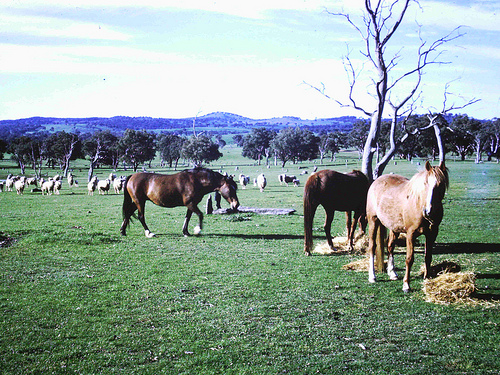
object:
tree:
[179, 137, 224, 168]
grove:
[340, 111, 498, 163]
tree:
[159, 135, 186, 168]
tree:
[123, 131, 155, 170]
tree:
[86, 134, 122, 171]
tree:
[48, 130, 80, 177]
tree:
[270, 128, 313, 168]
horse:
[126, 167, 239, 236]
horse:
[366, 160, 448, 293]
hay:
[419, 269, 476, 303]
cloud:
[404, 29, 433, 43]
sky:
[0, 0, 499, 114]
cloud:
[0, 8, 138, 45]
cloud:
[408, 44, 500, 59]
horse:
[303, 168, 368, 255]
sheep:
[85, 175, 100, 196]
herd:
[1, 172, 267, 195]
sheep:
[256, 173, 267, 193]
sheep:
[239, 172, 251, 190]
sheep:
[113, 175, 123, 195]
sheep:
[13, 176, 27, 196]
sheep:
[4, 174, 16, 192]